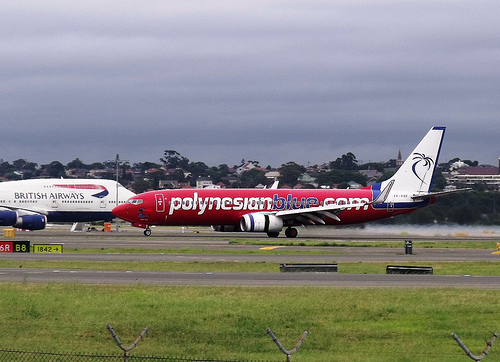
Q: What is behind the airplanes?
A: A line of trees and houses.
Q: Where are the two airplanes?
A: On the tarmac.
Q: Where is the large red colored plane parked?
A: On a gray landing strip.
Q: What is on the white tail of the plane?
A: Blue parts and a logo.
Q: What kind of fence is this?
A: Gray metal barbed wire.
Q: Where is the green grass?
A: On an airfield.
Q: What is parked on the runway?
A: A red colored plane.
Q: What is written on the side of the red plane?
A: Polynesian blue.com.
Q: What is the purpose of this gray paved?
A: Runway for plane.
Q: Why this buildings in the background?
A: The surrounding of airport.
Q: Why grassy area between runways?
A: No pavement.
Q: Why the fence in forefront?
A: An wall of airport.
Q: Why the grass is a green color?
A: A natural color of grass.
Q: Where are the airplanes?
A: On the runway.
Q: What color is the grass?
A: Green.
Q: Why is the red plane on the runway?
A: It just landed.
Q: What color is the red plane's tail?
A: White.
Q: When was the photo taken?
A: Daytime.